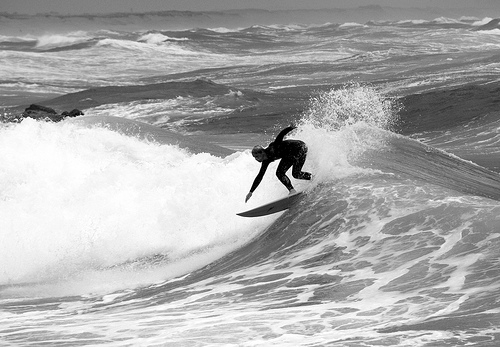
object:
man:
[245, 121, 314, 204]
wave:
[1, 114, 499, 307]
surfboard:
[235, 191, 305, 218]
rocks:
[3, 108, 83, 123]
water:
[1, 73, 499, 346]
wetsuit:
[249, 126, 313, 192]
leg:
[292, 146, 312, 180]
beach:
[0, 19, 500, 69]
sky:
[0, 0, 500, 5]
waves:
[0, 15, 499, 61]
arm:
[244, 161, 271, 203]